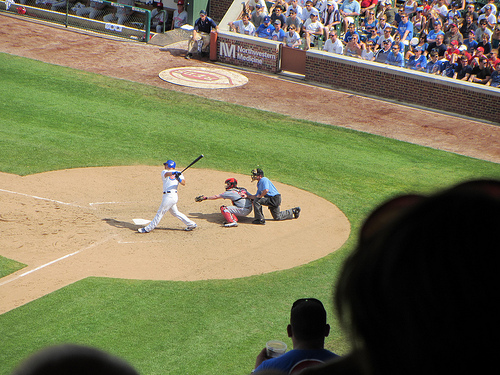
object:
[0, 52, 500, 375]
grass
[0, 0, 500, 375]
field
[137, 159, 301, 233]
people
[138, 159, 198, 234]
player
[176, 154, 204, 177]
bat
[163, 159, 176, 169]
helmet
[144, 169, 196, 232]
outfit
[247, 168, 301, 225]
man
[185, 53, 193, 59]
shoe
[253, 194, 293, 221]
pants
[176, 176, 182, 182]
glove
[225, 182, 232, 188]
mask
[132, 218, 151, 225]
plate